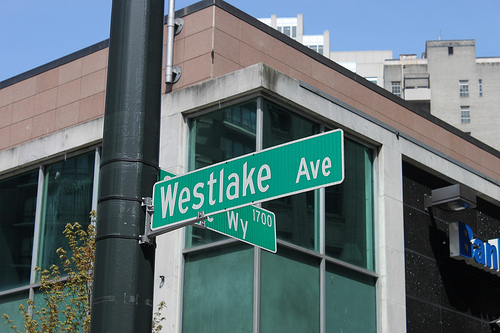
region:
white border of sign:
[309, 108, 350, 142]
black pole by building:
[77, 75, 174, 265]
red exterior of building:
[192, 17, 354, 74]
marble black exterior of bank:
[417, 198, 483, 326]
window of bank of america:
[310, 138, 379, 275]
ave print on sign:
[276, 138, 343, 181]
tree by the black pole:
[8, 209, 95, 326]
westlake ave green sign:
[149, 150, 371, 230]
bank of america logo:
[438, 214, 497, 274]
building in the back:
[328, 22, 498, 111]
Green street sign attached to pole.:
[149, 183, 343, 218]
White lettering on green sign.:
[155, 176, 308, 229]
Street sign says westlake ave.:
[161, 166, 336, 221]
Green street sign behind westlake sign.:
[166, 162, 291, 264]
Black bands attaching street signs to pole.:
[96, 154, 155, 261]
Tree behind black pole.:
[23, 215, 137, 330]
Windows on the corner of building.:
[201, 120, 348, 240]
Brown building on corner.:
[26, 67, 103, 113]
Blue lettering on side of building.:
[447, 228, 497, 281]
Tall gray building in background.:
[402, 38, 451, 115]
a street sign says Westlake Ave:
[132, 142, 368, 237]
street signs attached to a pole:
[61, 85, 366, 311]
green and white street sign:
[150, 123, 346, 255]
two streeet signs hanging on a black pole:
[73, 119, 360, 270]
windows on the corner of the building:
[182, 113, 385, 332]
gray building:
[385, 41, 499, 146]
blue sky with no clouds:
[3, 1, 499, 98]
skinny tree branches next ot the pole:
[1, 209, 169, 331]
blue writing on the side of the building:
[442, 220, 499, 265]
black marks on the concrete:
[261, 64, 286, 88]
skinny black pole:
[86, 3, 183, 331]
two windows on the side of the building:
[452, 73, 476, 125]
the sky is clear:
[329, 3, 384, 35]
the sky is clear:
[376, 21, 433, 45]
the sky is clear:
[4, 14, 79, 66]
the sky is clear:
[333, 11, 435, 32]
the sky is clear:
[367, 6, 429, 58]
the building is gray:
[379, 49, 496, 109]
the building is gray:
[368, 38, 493, 85]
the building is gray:
[429, 27, 498, 128]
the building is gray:
[324, 35, 446, 95]